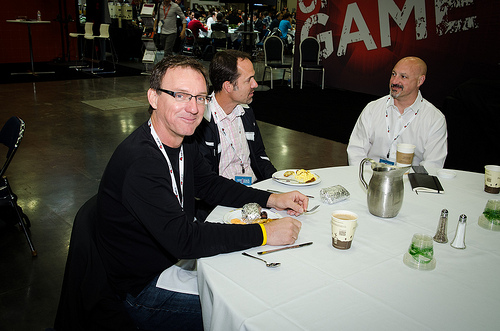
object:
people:
[211, 12, 230, 48]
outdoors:
[179, 7, 262, 36]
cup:
[330, 209, 360, 251]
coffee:
[358, 157, 411, 218]